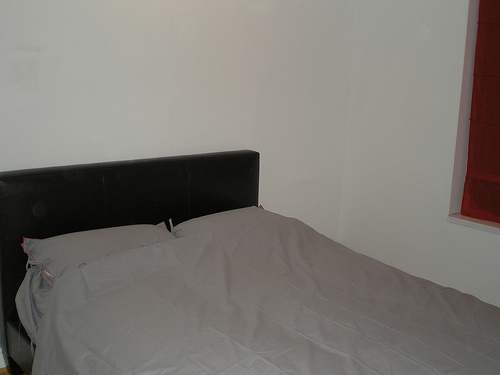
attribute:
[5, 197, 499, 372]
comforter — white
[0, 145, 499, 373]
bed — wooden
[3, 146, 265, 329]
headboard — black, leather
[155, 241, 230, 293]
blanket — white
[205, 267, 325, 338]
fabric — white, cover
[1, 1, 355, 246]
walls — white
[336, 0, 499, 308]
walls — white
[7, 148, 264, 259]
headboard — dark, rectangular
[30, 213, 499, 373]
cover — white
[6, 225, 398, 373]
fabric — white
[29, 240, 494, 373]
fabric — white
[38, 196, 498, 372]
sheet — grey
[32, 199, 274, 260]
pillows — white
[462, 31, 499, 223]
curtain — red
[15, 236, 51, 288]
stitching — pink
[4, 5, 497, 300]
wall — white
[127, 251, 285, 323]
frabric — white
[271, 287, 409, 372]
frabric — white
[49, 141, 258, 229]
headboard — leather